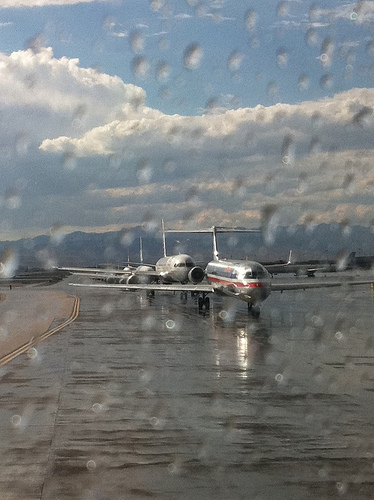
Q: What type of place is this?
A: It is a road.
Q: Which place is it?
A: It is a road.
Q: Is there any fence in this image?
A: No, there are no fences.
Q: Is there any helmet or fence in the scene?
A: No, there are no fences or helmets.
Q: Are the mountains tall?
A: Yes, the mountains are tall.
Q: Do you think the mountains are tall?
A: Yes, the mountains are tall.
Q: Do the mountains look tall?
A: Yes, the mountains are tall.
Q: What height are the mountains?
A: The mountains are tall.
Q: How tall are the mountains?
A: The mountains are tall.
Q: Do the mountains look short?
A: No, the mountains are tall.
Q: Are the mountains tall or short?
A: The mountains are tall.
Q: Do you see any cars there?
A: No, there are no cars.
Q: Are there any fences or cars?
A: No, there are no cars or fences.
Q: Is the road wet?
A: Yes, the road is wet.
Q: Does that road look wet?
A: Yes, the road is wet.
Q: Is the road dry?
A: No, the road is wet.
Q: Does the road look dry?
A: No, the road is wet.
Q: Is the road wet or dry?
A: The road is wet.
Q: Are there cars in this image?
A: No, there are no cars.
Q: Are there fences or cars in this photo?
A: No, there are no cars or fences.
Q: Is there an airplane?
A: Yes, there are airplanes.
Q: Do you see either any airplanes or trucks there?
A: Yes, there are airplanes.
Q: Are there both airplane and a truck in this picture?
A: No, there are airplanes but no trucks.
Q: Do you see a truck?
A: No, there are no trucks.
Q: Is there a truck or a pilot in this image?
A: No, there are no trucks or pilots.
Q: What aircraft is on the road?
A: The aircraft is airplanes.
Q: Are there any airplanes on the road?
A: Yes, there are airplanes on the road.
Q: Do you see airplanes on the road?
A: Yes, there are airplanes on the road.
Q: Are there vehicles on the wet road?
A: No, there are airplanes on the road.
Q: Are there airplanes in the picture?
A: Yes, there is an airplane.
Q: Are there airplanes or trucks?
A: Yes, there is an airplane.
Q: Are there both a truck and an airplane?
A: No, there is an airplane but no trucks.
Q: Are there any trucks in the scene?
A: No, there are no trucks.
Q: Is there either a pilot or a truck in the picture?
A: No, there are no trucks or pilots.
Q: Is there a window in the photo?
A: Yes, there is a window.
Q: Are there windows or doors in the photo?
A: Yes, there is a window.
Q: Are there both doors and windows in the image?
A: No, there is a window but no doors.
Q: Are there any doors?
A: No, there are no doors.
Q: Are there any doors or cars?
A: No, there are no doors or cars.